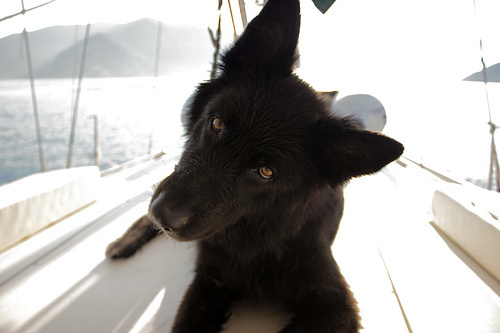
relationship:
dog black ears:
[149, 41, 365, 302] [241, 4, 401, 171]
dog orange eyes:
[149, 41, 365, 302] [206, 110, 286, 191]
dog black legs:
[149, 41, 365, 302] [186, 275, 358, 332]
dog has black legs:
[149, 41, 365, 302] [186, 275, 358, 332]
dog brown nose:
[149, 41, 365, 302] [149, 185, 197, 230]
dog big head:
[149, 41, 365, 302] [166, 73, 323, 229]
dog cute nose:
[149, 41, 365, 302] [149, 185, 197, 230]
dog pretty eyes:
[149, 41, 365, 302] [206, 110, 286, 191]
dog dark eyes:
[149, 41, 365, 302] [206, 110, 286, 191]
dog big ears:
[149, 41, 365, 302] [241, 4, 401, 171]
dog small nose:
[149, 41, 365, 302] [149, 185, 197, 230]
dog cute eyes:
[149, 41, 365, 302] [206, 110, 286, 191]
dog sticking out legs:
[149, 41, 365, 302] [186, 275, 358, 332]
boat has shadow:
[29, 188, 107, 329] [87, 273, 141, 317]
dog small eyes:
[149, 41, 365, 302] [206, 110, 286, 191]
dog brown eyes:
[149, 41, 365, 302] [206, 110, 286, 191]